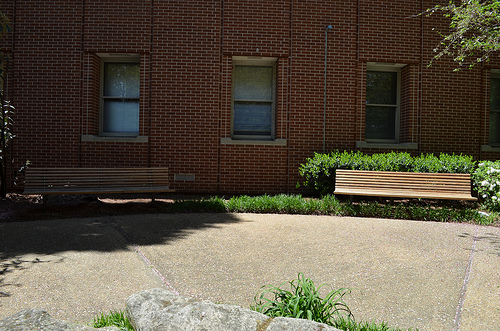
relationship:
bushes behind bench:
[296, 146, 475, 197] [331, 165, 479, 209]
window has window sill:
[99, 55, 140, 135] [82, 131, 148, 143]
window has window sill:
[231, 63, 272, 136] [220, 134, 286, 147]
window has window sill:
[364, 69, 397, 145] [353, 139, 419, 149]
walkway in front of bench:
[2, 213, 498, 331] [21, 163, 175, 210]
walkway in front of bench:
[2, 213, 498, 331] [331, 165, 479, 209]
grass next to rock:
[247, 272, 420, 330] [84, 287, 346, 329]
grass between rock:
[94, 302, 136, 331] [84, 287, 346, 329]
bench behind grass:
[331, 165, 479, 209] [170, 195, 490, 227]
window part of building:
[99, 55, 140, 135] [1, 1, 497, 193]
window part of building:
[231, 63, 272, 136] [1, 1, 497, 193]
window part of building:
[364, 69, 397, 145] [1, 1, 497, 193]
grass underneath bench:
[170, 195, 490, 227] [331, 165, 479, 209]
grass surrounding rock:
[247, 272, 420, 330] [84, 287, 346, 329]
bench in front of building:
[21, 163, 175, 210] [1, 1, 497, 193]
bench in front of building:
[331, 165, 479, 209] [1, 1, 497, 193]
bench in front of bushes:
[331, 165, 479, 209] [296, 146, 475, 197]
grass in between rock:
[94, 302, 136, 331] [84, 287, 346, 329]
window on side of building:
[99, 55, 140, 135] [1, 1, 497, 193]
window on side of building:
[231, 63, 272, 136] [1, 1, 497, 193]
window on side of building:
[364, 69, 397, 145] [1, 1, 497, 193]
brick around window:
[77, 47, 150, 138] [99, 55, 140, 135]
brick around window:
[219, 47, 289, 140] [231, 63, 272, 136]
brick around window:
[353, 53, 419, 146] [364, 69, 397, 145]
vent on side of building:
[172, 170, 198, 184] [1, 1, 497, 193]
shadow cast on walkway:
[1, 189, 254, 301] [2, 213, 498, 331]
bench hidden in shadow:
[21, 163, 175, 210] [1, 189, 254, 301]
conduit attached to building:
[320, 22, 334, 155] [1, 1, 497, 193]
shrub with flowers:
[470, 159, 499, 219] [478, 161, 499, 205]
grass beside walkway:
[170, 195, 490, 227] [2, 213, 498, 331]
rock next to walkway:
[84, 287, 346, 329] [2, 213, 498, 331]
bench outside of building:
[21, 163, 175, 210] [1, 1, 497, 193]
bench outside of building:
[331, 165, 479, 209] [1, 1, 497, 193]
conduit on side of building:
[320, 22, 334, 155] [1, 1, 497, 193]